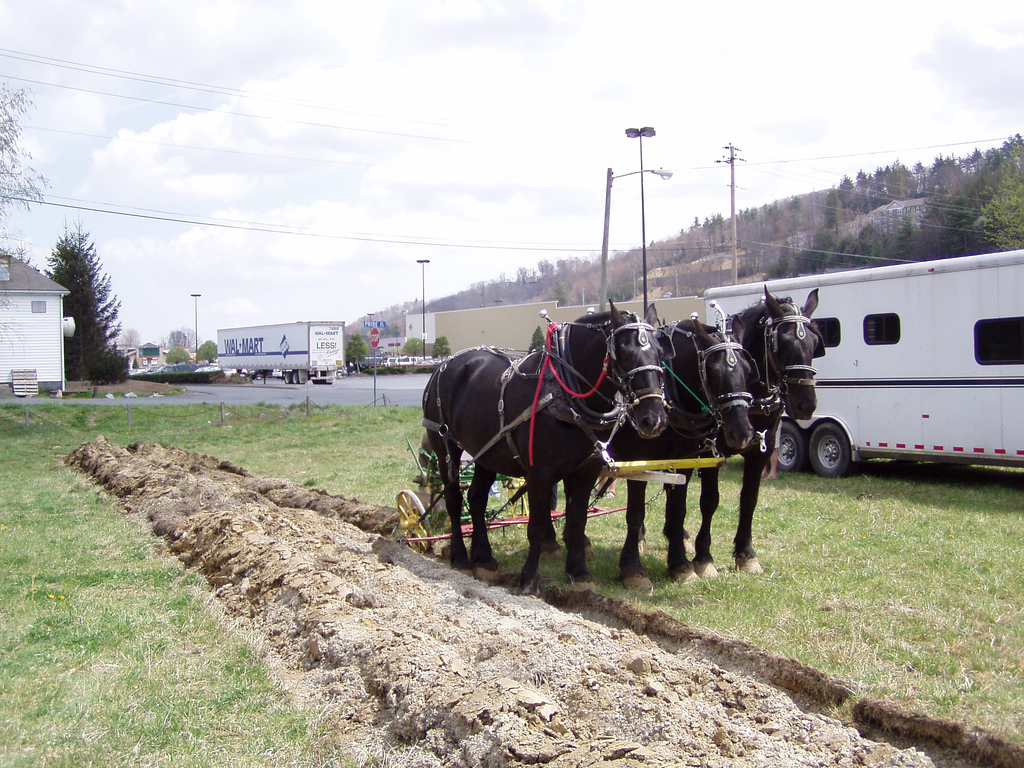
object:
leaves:
[969, 137, 1019, 249]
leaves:
[43, 220, 122, 374]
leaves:
[636, 235, 677, 274]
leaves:
[429, 281, 486, 312]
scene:
[370, 624, 416, 641]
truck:
[217, 320, 345, 386]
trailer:
[707, 242, 1024, 482]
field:
[0, 392, 1024, 768]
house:
[0, 254, 69, 391]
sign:
[369, 328, 380, 349]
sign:
[362, 320, 386, 328]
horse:
[419, 301, 665, 585]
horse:
[422, 284, 819, 594]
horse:
[618, 314, 760, 587]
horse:
[692, 285, 823, 579]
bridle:
[510, 308, 663, 473]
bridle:
[651, 302, 757, 451]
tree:
[928, 142, 994, 234]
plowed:
[55, 430, 1002, 766]